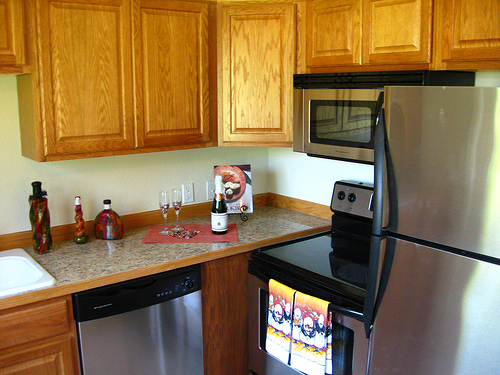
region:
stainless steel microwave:
[277, 52, 498, 202]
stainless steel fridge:
[365, 63, 499, 373]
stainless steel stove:
[222, 178, 393, 373]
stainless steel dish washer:
[57, 257, 224, 374]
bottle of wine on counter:
[206, 170, 256, 246]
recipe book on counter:
[202, 144, 272, 239]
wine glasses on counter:
[144, 177, 196, 249]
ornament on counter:
[25, 170, 152, 270]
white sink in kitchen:
[0, 232, 67, 317]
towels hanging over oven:
[251, 269, 381, 374]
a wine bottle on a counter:
[194, 173, 234, 249]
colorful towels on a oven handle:
[246, 300, 336, 372]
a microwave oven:
[275, 73, 393, 168]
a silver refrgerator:
[335, 77, 492, 360]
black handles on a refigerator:
[343, 99, 408, 341]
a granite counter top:
[22, 177, 328, 304]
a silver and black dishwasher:
[63, 265, 210, 373]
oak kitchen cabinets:
[8, 4, 487, 165]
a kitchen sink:
[2, 232, 48, 292]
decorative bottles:
[1, 186, 138, 244]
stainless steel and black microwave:
[282, 70, 481, 180]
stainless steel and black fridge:
[352, 75, 498, 373]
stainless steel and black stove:
[237, 172, 376, 374]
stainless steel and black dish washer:
[59, 281, 221, 373]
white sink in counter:
[3, 240, 67, 316]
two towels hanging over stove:
[251, 278, 366, 373]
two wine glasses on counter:
[137, 179, 202, 260]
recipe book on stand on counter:
[204, 141, 270, 246]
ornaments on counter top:
[14, 169, 148, 275]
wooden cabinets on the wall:
[57, 29, 278, 144]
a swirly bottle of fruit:
[66, 184, 104, 258]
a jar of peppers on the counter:
[25, 177, 66, 269]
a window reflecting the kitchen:
[316, 106, 363, 139]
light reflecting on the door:
[469, 279, 492, 364]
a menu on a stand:
[231, 168, 280, 219]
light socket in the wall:
[176, 179, 203, 204]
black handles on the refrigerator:
[362, 121, 397, 327]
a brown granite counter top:
[71, 255, 110, 276]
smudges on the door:
[429, 109, 457, 147]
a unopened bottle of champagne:
[203, 173, 230, 248]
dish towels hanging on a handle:
[271, 280, 331, 374]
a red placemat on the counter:
[199, 226, 209, 244]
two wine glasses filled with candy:
[150, 178, 197, 236]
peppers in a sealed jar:
[92, 191, 128, 241]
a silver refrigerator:
[384, 96, 488, 372]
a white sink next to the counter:
[4, 249, 46, 291]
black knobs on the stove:
[334, 187, 359, 204]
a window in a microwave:
[311, 101, 364, 146]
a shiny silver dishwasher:
[83, 306, 213, 366]